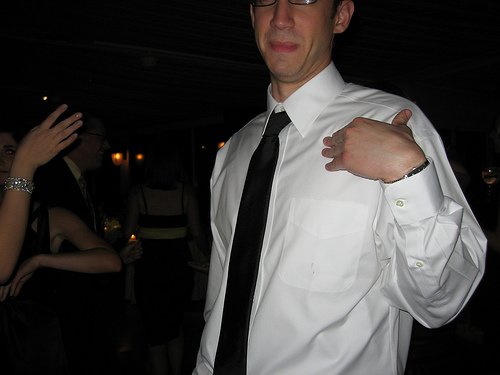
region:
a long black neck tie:
[192, 85, 282, 372]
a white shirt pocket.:
[279, 186, 374, 307]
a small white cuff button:
[393, 198, 407, 210]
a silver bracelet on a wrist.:
[6, 173, 34, 198]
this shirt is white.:
[275, 319, 328, 347]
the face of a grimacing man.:
[239, 3, 350, 87]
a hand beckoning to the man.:
[19, 98, 86, 166]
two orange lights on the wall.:
[101, 148, 148, 170]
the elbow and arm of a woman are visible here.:
[1, 210, 128, 307]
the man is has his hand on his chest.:
[308, 105, 437, 180]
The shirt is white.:
[282, 210, 359, 326]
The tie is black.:
[247, 165, 269, 215]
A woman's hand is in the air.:
[18, 101, 85, 168]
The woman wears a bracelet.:
[2, 176, 35, 193]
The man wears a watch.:
[404, 159, 428, 178]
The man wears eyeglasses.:
[260, 0, 322, 10]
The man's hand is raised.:
[320, 110, 425, 180]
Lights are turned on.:
[111, 150, 144, 162]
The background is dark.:
[0, 11, 222, 75]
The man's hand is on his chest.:
[322, 107, 423, 181]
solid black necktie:
[207, 98, 292, 371]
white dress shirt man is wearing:
[195, 68, 477, 373]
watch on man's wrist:
[380, 158, 430, 187]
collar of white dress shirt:
[258, 68, 338, 139]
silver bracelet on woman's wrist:
[5, 171, 30, 196]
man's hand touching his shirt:
[312, 113, 429, 188]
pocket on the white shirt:
[273, 188, 370, 293]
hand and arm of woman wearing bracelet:
[2, 101, 79, 291]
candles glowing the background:
[104, 143, 156, 248]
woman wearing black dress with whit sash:
[125, 147, 202, 336]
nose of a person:
[271, 12, 294, 35]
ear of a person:
[317, 8, 362, 46]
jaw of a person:
[254, 56, 316, 98]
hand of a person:
[310, 70, 431, 182]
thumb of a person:
[382, 90, 422, 128]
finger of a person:
[316, 91, 373, 176]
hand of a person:
[11, 90, 100, 159]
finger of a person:
[16, 96, 106, 173]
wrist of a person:
[0, 168, 48, 192]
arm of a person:
[23, 240, 120, 281]